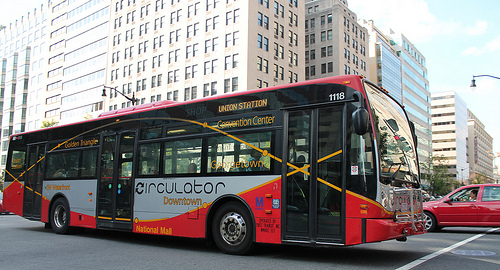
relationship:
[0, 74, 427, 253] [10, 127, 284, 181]
bus has side windows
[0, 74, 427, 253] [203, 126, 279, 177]
buses large windows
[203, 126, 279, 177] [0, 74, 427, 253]
clear windows of bus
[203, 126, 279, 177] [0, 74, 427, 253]
large windows on bus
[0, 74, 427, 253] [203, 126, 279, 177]
bus has large windows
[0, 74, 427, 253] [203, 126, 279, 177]
bus with windows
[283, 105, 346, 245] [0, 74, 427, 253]
side doors on bus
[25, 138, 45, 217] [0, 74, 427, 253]
rear side door of bus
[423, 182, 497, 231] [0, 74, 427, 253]
car next to bus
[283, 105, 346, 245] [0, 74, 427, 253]
door of bus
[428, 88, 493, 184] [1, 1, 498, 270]
building in city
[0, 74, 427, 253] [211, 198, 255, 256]
bus has a large tire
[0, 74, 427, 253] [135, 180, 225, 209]
bus has writting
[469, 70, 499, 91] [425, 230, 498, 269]
street light over street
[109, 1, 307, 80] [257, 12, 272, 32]
building has windows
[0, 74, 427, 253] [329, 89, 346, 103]
bus has an id number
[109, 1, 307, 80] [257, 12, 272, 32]
building with windows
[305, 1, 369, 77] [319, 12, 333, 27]
buildings have windows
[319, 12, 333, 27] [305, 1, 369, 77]
windows on highrise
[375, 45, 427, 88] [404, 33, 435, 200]
glass windows on highrise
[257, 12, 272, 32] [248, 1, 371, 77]
small windows on building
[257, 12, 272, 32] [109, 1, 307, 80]
windows on two sides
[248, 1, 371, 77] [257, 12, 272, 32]
building with windows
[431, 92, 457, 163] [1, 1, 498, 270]
windows overlooking city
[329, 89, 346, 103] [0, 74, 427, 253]
white numbers on bus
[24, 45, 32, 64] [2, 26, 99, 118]
windows on building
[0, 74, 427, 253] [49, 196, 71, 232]
bus has a rear tire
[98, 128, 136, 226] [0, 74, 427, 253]
center door of a bus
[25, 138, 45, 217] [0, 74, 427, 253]
door of bus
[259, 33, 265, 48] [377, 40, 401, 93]
window of a building